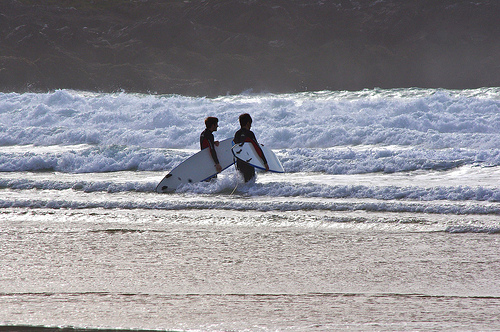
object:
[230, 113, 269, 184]
man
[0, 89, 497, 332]
ocean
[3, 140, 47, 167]
wave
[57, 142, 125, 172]
wave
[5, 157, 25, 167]
ripple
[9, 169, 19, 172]
ripple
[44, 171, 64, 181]
ripple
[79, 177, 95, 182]
ripple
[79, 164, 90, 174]
ripple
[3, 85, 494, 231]
water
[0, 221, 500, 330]
beach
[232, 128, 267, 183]
suit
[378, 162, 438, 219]
ground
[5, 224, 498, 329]
water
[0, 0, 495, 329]
scene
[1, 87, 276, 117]
waves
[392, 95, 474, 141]
wave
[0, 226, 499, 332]
calm water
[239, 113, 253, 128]
head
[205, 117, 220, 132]
head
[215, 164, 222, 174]
hands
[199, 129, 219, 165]
suits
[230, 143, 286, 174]
board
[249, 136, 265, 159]
arm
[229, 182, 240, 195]
cord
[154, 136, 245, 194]
board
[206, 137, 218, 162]
arms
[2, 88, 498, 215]
water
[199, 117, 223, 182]
man